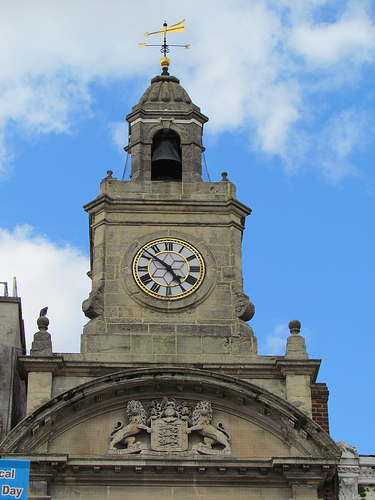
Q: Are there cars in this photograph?
A: No, there are no cars.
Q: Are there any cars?
A: No, there are no cars.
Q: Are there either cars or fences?
A: No, there are no cars or fences.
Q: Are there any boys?
A: No, there are no boys.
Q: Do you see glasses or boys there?
A: No, there are no boys or glasses.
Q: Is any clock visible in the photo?
A: Yes, there is a clock.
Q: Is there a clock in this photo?
A: Yes, there is a clock.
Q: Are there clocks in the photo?
A: Yes, there is a clock.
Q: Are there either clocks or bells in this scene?
A: Yes, there is a clock.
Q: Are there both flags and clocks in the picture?
A: No, there is a clock but no flags.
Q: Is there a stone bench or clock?
A: Yes, there is a stone clock.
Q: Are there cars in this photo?
A: No, there are no cars.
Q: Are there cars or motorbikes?
A: No, there are no cars or motorbikes.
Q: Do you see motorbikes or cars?
A: No, there are no cars or motorbikes.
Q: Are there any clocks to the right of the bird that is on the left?
A: Yes, there is a clock to the right of the bird.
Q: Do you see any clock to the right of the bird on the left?
A: Yes, there is a clock to the right of the bird.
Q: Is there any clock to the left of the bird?
A: No, the clock is to the right of the bird.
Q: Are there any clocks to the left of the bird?
A: No, the clock is to the right of the bird.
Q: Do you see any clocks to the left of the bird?
A: No, the clock is to the right of the bird.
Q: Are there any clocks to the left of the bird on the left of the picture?
A: No, the clock is to the right of the bird.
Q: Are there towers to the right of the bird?
A: No, there is a clock to the right of the bird.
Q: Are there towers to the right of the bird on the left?
A: No, there is a clock to the right of the bird.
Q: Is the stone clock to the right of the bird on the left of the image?
A: Yes, the clock is to the right of the bird.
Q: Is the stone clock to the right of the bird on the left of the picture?
A: Yes, the clock is to the right of the bird.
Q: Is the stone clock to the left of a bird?
A: No, the clock is to the right of a bird.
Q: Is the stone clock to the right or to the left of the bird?
A: The clock is to the right of the bird.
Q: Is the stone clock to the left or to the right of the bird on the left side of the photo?
A: The clock is to the right of the bird.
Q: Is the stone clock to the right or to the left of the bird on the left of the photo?
A: The clock is to the right of the bird.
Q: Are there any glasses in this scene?
A: No, there are no glasses.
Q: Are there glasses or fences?
A: No, there are no glasses or fences.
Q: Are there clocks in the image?
A: Yes, there is a clock.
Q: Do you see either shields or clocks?
A: Yes, there is a clock.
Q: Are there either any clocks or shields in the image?
A: Yes, there is a clock.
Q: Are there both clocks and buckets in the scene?
A: No, there is a clock but no buckets.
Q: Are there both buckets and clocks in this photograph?
A: No, there is a clock but no buckets.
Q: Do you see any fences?
A: No, there are no fences.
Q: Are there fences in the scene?
A: No, there are no fences.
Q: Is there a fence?
A: No, there are no fences.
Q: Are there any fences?
A: No, there are no fences.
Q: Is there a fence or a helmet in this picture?
A: No, there are no fences or helmets.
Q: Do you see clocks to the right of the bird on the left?
A: Yes, there is a clock to the right of the bird.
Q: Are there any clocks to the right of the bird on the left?
A: Yes, there is a clock to the right of the bird.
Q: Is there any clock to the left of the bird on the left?
A: No, the clock is to the right of the bird.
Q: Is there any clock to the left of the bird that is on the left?
A: No, the clock is to the right of the bird.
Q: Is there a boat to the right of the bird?
A: No, there is a clock to the right of the bird.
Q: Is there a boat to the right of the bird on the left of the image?
A: No, there is a clock to the right of the bird.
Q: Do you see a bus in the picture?
A: No, there are no buses.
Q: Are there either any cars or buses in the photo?
A: No, there are no buses or cars.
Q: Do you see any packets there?
A: No, there are no packets.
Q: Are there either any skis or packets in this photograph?
A: No, there are no packets or skis.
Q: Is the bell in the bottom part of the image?
A: No, the bell is in the top of the image.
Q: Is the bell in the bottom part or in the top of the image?
A: The bell is in the top of the image.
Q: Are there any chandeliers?
A: No, there are no chandeliers.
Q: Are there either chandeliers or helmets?
A: No, there are no chandeliers or helmets.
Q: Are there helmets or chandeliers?
A: No, there are no chandeliers or helmets.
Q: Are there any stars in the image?
A: Yes, there is a star.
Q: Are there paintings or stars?
A: Yes, there is a star.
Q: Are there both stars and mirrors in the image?
A: No, there is a star but no mirrors.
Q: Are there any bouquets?
A: No, there are no bouquets.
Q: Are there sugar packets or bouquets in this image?
A: No, there are no bouquets or sugar packets.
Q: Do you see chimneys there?
A: No, there are no chimneys.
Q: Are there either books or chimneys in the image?
A: No, there are no chimneys or books.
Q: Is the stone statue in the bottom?
A: Yes, the statue is in the bottom of the image.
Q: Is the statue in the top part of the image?
A: No, the statue is in the bottom of the image.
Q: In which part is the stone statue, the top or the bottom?
A: The statue is in the bottom of the image.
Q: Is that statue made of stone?
A: Yes, the statue is made of stone.